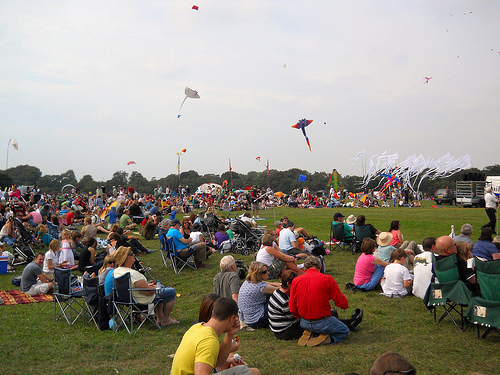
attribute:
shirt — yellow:
[172, 320, 219, 372]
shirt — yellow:
[172, 314, 214, 373]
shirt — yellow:
[164, 326, 220, 374]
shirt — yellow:
[284, 268, 352, 321]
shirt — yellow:
[169, 316, 218, 373]